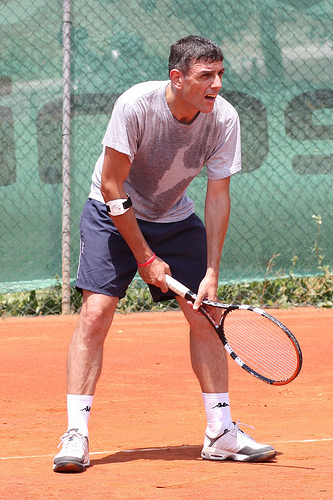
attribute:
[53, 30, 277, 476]
tennis player — man, tired, waiting for pitch, sweating, playing tennis, sweaty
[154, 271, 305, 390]
tennis racket — black, white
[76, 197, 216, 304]
shorts — blue, dark blue, navy blue, cotton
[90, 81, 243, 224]
t-shirt — wet, grey, full of sweat, cotton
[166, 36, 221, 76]
hair — dark, damp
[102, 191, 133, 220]
wrist band — black, white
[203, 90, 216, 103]
mouth — open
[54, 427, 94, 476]
shoe — white, black, grey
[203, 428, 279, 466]
shoe — white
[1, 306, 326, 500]
court — clay, bare, dirt, fenced, brown, sandy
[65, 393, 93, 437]
sock — white, black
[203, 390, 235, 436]
sock — white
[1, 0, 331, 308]
fence — meshed wire, chain link, metal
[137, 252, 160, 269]
arm band — red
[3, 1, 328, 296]
background court — green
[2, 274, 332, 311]
plants — green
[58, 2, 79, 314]
fence post — metal, grey